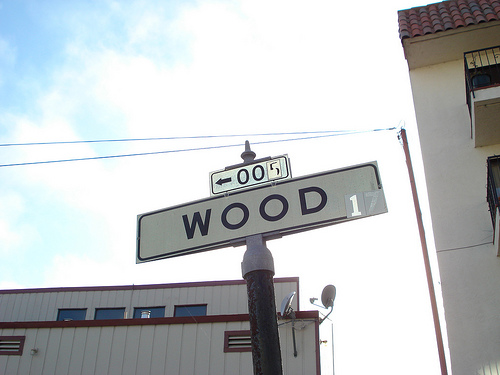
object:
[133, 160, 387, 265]
sign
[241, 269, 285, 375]
pole